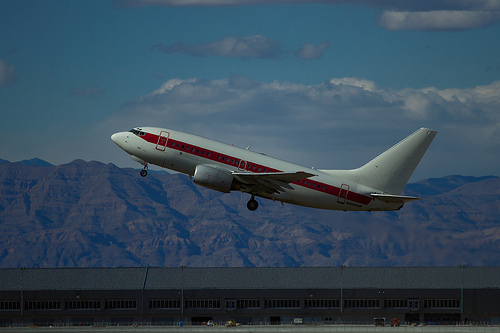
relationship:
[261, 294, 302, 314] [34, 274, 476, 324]
windows on building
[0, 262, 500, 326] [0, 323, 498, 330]
building on ground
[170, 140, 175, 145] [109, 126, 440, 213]
window on airplane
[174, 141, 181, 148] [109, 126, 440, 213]
window on airplane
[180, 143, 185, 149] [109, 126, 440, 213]
window on airplane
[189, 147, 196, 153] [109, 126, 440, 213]
window on airplane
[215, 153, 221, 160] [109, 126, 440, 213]
window on airplane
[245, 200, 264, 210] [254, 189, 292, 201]
wheel on bottom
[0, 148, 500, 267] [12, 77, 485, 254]
mountains in background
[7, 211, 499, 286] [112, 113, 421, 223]
mountains airplane beside airplane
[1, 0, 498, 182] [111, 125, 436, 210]
sky above airplane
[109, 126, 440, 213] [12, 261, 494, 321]
airplane flying away from airport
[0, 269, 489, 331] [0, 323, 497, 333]
building near to ground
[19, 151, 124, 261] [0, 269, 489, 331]
two men next building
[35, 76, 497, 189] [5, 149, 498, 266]
cloud near mountain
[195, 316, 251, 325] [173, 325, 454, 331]
cars in ground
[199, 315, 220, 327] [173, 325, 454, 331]
cars in ground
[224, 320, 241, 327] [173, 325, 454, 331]
cars in ground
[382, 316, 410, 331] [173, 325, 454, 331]
cars in ground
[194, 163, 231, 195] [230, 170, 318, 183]
engine in wing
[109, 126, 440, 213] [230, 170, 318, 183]
airplane has wing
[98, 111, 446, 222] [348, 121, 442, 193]
airplane has tail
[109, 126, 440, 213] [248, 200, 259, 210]
airplane has wheel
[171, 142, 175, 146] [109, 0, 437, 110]
window in plane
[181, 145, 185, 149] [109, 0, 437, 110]
window in plane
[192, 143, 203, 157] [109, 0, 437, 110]
window in plane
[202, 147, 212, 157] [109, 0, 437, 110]
window in plane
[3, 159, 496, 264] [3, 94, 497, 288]
hills in background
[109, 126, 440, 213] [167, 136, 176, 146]
airplane has window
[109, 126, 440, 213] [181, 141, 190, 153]
airplane has window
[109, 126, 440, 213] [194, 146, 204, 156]
airplane has window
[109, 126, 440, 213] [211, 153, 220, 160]
airplane has window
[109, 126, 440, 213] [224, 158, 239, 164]
airplane has window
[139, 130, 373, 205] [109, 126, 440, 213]
stripe on airplane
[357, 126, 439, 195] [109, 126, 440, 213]
tail on airplane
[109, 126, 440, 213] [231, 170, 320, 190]
airplane has wing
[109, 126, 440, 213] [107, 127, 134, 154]
airplane has nose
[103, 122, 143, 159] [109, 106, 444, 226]
nose on plane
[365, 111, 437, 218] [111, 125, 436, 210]
tail on airplane